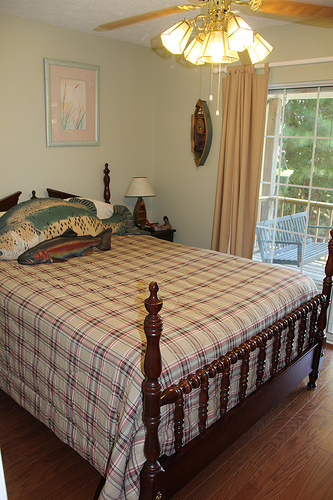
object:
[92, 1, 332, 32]
celing fan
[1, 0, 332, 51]
ceiling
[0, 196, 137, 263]
pillows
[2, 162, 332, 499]
bed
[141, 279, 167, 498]
post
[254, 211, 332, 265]
bench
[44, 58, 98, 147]
picture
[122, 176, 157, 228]
lamp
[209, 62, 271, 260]
curtains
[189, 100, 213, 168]
boat decor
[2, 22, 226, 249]
wall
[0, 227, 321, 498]
bed spread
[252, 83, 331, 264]
window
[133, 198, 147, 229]
canoe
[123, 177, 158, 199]
shade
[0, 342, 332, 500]
floor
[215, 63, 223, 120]
strings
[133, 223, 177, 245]
nightstand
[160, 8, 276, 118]
lights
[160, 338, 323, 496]
slats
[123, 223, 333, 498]
foot portian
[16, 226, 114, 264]
fish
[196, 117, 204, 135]
fish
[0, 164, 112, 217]
head board